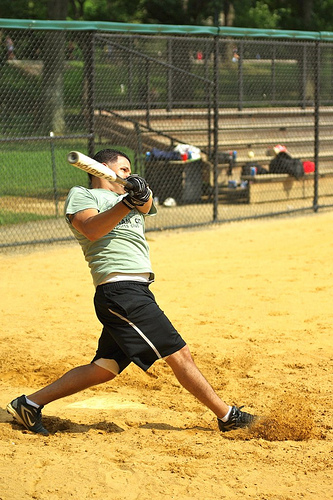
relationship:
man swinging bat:
[6, 148, 261, 437] [67, 151, 150, 190]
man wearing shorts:
[6, 148, 261, 437] [90, 280, 186, 374]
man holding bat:
[76, 155, 207, 335] [50, 147, 141, 186]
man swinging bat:
[6, 148, 261, 437] [66, 150, 136, 190]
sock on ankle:
[218, 402, 238, 420] [214, 404, 241, 421]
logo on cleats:
[24, 410, 37, 427] [5, 392, 51, 437]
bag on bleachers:
[269, 151, 304, 181] [120, 92, 329, 195]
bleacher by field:
[93, 105, 332, 205] [1, 205, 331, 286]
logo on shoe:
[26, 412, 36, 427] [5, 394, 47, 435]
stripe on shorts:
[106, 307, 162, 357] [90, 280, 186, 374]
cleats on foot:
[217, 405, 259, 433] [192, 383, 277, 448]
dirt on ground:
[211, 238, 241, 247] [2, 241, 327, 376]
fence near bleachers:
[9, 21, 324, 246] [96, 104, 331, 197]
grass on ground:
[2, 146, 143, 198] [0, 143, 332, 498]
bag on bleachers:
[271, 143, 309, 185] [85, 36, 332, 229]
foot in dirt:
[213, 404, 272, 434] [172, 281, 321, 496]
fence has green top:
[9, 21, 324, 246] [134, 8, 256, 64]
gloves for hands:
[122, 181, 156, 210] [119, 171, 152, 206]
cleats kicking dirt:
[209, 404, 276, 431] [221, 403, 287, 443]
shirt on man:
[78, 188, 163, 298] [60, 139, 266, 429]